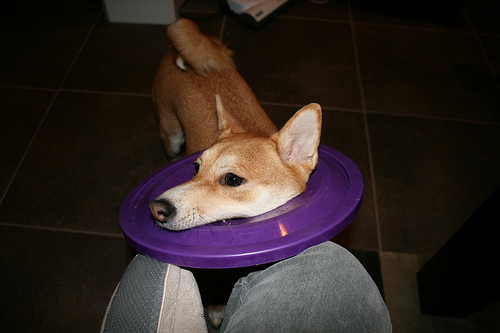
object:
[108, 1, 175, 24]
wall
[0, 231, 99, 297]
floor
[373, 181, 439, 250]
tile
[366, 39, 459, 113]
tile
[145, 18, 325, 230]
dog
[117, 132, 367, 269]
disc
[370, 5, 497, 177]
floor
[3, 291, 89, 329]
floor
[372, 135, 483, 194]
ground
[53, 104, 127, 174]
floor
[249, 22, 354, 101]
tile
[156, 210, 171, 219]
hole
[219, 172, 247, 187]
eye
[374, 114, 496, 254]
floor tile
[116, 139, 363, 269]
frisbee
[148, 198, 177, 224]
nose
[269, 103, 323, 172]
ear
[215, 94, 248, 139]
ear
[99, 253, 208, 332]
shoe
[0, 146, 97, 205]
tile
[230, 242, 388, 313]
knee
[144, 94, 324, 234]
dogs head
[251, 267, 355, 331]
jeans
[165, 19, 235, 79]
tail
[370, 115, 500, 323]
table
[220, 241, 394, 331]
human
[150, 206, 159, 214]
tip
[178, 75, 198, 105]
fur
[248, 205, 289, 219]
neck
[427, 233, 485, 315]
black leg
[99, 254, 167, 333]
sole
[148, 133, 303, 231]
face